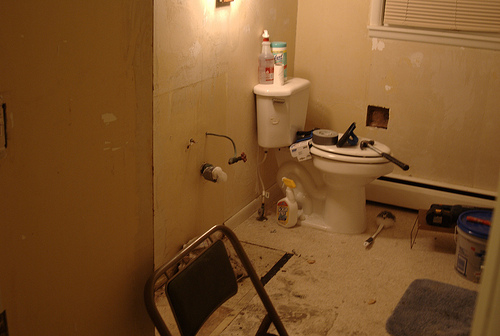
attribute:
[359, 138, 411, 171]
hammer — black, silver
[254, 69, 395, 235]
toilet — white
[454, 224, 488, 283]
bucket — gray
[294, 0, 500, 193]
wall — white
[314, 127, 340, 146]
duct tape — grey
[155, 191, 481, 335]
floor — dirty, broken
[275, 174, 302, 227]
spray bottle — white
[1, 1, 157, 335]
wall — damage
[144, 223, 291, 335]
stool — metal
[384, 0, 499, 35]
blinds — horizontal